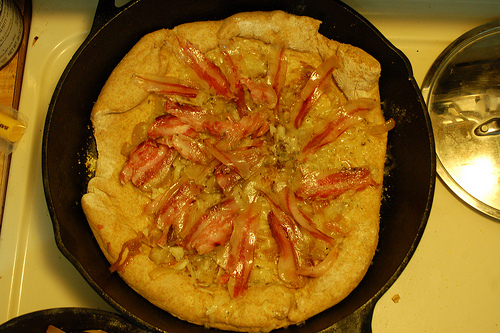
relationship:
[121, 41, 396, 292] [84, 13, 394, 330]
onions on fajita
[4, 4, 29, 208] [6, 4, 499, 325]
cabinet next to stove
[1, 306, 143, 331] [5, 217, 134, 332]
skillet in corner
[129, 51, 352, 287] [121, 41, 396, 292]
cabbage under onions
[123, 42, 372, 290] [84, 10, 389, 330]
bacon on fajita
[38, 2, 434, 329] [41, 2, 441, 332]
iron frying pan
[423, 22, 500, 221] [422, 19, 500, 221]
metal pot lid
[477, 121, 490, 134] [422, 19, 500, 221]
screw in lid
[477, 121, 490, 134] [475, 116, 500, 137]
screw in handle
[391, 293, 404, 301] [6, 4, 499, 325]
crumbs on stove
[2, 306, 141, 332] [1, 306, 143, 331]
edge of pan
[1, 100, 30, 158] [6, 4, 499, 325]
plastic next to stove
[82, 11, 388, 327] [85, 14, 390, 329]
golden thick crust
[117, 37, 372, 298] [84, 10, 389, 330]
sausage on fajita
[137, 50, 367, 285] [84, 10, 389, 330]
cheese on fajita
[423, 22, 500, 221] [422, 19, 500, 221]
silver pot lid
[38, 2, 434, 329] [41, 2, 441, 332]
iron black skillet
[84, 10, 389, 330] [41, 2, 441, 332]
fajita in skillet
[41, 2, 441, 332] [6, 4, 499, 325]
pan on stove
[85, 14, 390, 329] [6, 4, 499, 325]
crust on stove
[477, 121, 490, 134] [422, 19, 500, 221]
bolt on lid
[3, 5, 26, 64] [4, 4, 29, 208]
jar on counter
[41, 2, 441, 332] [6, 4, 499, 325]
skillet on stove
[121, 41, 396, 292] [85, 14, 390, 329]
onions atop bread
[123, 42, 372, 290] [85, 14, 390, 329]
bacon atop bread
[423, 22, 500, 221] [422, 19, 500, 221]
steel pot top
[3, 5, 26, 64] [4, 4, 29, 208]
can on counter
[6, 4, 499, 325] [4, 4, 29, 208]
stove near counter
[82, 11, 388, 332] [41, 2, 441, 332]
cornbread in skillet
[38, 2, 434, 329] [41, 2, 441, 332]
iron small skillet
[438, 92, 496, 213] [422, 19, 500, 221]
reflection in lid